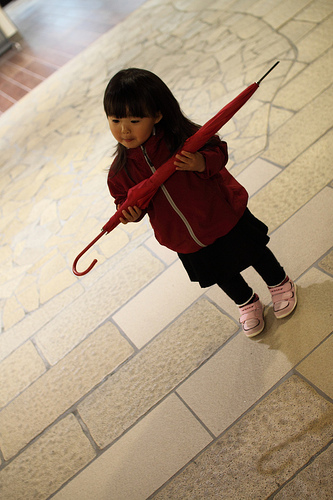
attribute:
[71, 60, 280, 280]
umbrella — red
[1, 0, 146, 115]
tiles — brick styled, red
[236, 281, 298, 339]
sneakers — pink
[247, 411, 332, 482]
stain — hook shaped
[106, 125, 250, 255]
hoodie — red, zipped up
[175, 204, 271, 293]
skirt — black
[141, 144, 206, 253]
zipper — white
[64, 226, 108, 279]
umbrella hook — red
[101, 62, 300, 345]
girl — little, standing, young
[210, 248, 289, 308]
tights — black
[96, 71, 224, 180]
hair — black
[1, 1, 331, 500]
floor — white, brown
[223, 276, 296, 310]
socks — black